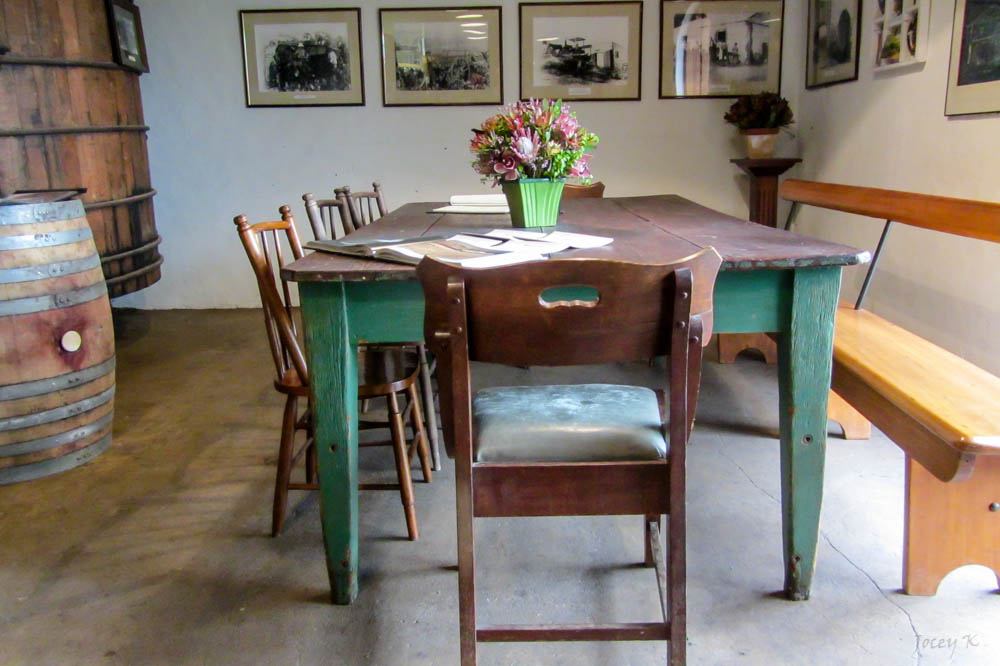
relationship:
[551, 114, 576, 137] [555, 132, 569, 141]
flower growing on stem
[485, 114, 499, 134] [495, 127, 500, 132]
flower growing on stem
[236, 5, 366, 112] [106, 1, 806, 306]
picture hanging on wall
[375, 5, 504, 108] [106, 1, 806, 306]
picture hanging on wall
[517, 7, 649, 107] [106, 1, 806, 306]
picture hanging on wall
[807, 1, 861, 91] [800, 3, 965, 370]
picture hanging on wall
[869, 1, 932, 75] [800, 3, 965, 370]
picture hanging on wall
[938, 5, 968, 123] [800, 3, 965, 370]
picture hanging on wall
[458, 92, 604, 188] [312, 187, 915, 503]
flowers are on table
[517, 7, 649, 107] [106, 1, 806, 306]
picture on wall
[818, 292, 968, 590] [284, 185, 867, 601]
seat along table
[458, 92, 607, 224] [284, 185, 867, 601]
flowers on table